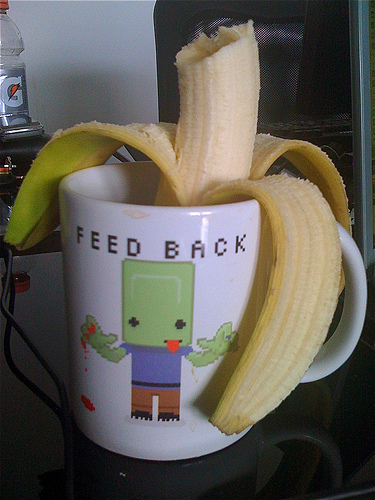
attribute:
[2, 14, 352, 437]
banana — yellow, peeled, bite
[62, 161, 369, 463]
mug — white, reflective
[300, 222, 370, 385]
handle — white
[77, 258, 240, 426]
figure — green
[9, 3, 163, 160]
wall — white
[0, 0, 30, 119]
bottle — empty, reflective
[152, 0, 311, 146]
chair — black